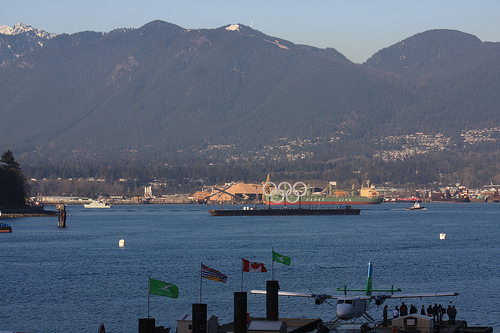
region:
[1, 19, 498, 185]
the big mountain in the distance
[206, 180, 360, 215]
the black boat in the water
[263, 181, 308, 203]
the olympic rings on the boat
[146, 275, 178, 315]
the green flag on the wooden post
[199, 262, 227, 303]
the flag on the wooden post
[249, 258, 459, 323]
the airplane on the dock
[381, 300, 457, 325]
the group of people on the dock near the airplane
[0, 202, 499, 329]
the large body of water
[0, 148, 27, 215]
the trees near the water's edge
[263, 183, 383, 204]
the red, green and white boat in the back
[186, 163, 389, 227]
A boat in the water.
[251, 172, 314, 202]
The boat has Olympic symbol on it.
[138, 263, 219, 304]
Flags flying in the air.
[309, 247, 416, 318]
A plane on the water.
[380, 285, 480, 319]
People standing by the plane.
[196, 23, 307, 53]
Snow on top of the mountain.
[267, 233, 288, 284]
A green flag on the pole.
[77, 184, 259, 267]
The water is blue.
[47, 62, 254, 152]
trees on the mountains.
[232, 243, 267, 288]
A red and white flag on the pole.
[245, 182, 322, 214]
olympic rings logo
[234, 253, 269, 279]
the official flag of canada blowing in the wind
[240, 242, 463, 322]
a sea plane parked on the water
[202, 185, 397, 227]
two cargo ships on the water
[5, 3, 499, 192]
tall mountain in the distance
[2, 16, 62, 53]
a snow-covered mountain peak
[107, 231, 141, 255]
a bouey in the water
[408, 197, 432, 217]
small tug boat in the harbor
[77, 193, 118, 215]
a boat in the water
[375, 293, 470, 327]
passengers waiting for the sea plane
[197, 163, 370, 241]
A boat on the water.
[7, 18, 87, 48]
Snow on the mountain.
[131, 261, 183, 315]
A green flag on the pole.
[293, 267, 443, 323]
A plane by the water.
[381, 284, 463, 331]
People standing by the plane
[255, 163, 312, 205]
The Olympic symbol on the boat.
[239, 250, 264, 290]
The red and white flag on the pole.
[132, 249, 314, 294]
Flags flyingin the air.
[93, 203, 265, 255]
The water is blue and calm.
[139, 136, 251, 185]
Trees on the mountain.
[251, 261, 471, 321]
airplane on pontoons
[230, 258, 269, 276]
national flag of Canada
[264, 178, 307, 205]
five ring logo of the olympics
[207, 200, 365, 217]
large black barge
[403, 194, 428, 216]
a smaller boat near far shore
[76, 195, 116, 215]
a large white motor boat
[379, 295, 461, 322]
a group of people stand near the plane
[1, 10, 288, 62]
snow covered mountain tops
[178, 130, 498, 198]
a city on the mountain side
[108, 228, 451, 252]
two white bouys in the water